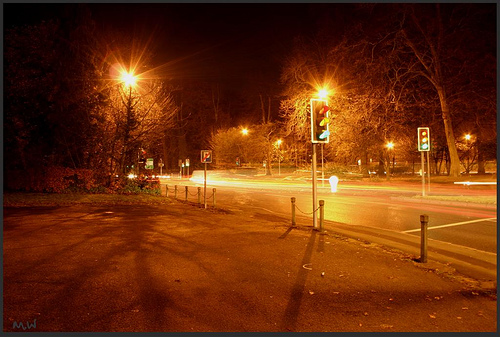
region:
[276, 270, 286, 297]
the view of a white wall and chairs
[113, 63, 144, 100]
street light burning brightly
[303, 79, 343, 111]
street light burning brightly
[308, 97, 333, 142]
traffic light with red yellow and green lights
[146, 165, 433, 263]
silver metal poles lining the street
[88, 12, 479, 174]
trees in background behind street lamps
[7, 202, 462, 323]
concrete lot next to street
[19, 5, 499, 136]
black clear night time sky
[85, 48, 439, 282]
this is a street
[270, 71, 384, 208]
these are street signals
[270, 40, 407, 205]
the signals are lit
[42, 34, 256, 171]
the light is orange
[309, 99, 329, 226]
traffic light on a metal pole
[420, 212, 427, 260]
grey metal street barrier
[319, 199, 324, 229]
grey metal street barrier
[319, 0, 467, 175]
large tree with no leaves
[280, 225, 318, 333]
shadow of a street light post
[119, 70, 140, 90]
a bright street light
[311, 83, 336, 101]
a bright street light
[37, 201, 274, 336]
the shadow of a tree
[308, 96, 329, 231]
traffic light is on a pole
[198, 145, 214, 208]
blue and white no parking sign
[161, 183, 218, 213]
pole and chain fence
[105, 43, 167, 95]
glare from a street light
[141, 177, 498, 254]
wet road at night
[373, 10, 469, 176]
tall leafless tree by road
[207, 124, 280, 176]
two small trees lit up by streetlight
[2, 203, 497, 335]
parking area is empty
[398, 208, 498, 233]
white line in road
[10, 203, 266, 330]
shadows cast by streetlight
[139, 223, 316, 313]
the road is empty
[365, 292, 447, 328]
debri on the road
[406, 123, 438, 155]
the light is orange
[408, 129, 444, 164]
the light is green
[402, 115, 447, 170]
the light is red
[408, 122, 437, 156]
the light is black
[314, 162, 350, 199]
light on the road